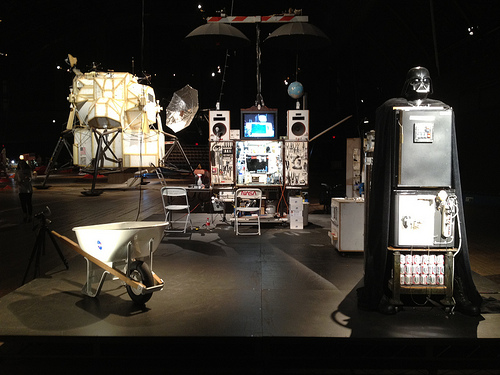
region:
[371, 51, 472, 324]
robot made with mask and boxes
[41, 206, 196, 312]
white wheelbarrow on dark floor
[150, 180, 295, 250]
two folding chairs that are open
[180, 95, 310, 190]
table with metal boxes of electronics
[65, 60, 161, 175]
structure composed of white panels and wood strips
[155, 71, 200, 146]
silver reflective umbrella on stand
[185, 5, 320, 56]
black umbrellas hanging from orange and white bar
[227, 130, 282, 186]
box with rectangular opening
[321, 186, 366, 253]
white cabinet trimmed in light wood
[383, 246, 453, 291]
rows of cans neatly stacked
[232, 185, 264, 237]
White folding chair with graffiti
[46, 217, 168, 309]
white metal and wood wheelbarrow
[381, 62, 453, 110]
Darth Vader head and cape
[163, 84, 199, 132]
light reflecting photographer's umbrella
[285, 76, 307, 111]
Globe of Earth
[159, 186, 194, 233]
Plain white metal folding chair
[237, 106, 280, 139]
Television screen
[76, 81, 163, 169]
taped up back of set piece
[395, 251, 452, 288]
Cans stacked in compartment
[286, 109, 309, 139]
White stereo speaker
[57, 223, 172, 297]
this is a wheelbarrow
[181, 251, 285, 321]
this is the floor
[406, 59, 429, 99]
this is a statue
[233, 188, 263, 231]
this is a chair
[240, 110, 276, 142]
this is a television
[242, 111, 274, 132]
the television is on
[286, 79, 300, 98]
this is a globe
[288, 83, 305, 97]
the globe is round in shape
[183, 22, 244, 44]
this is an umbrella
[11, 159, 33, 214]
this is a lady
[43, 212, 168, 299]
White wheelbarrow with wooden handles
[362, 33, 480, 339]
Large metal robot wearing black cape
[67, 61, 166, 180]
Yellow and white model spaceship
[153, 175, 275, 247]
Two gray folding chairs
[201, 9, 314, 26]
White and red sign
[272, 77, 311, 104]
Blue globe model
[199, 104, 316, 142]
Two white and black speakers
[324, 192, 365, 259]
Gray file cabinet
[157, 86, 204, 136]
Metallic flash screen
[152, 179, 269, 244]
two gray folding chairs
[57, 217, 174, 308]
wheel barrow with black tire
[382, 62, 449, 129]
head of Star Wars character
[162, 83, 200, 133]
silver umbrella for photography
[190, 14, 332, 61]
two black umbrellas side by side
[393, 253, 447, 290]
stacks of cans in box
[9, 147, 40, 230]
woman in black pants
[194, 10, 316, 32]
long orange and white board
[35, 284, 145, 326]
shadow of wheel barrow on floor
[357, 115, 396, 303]
black cape over three boxes